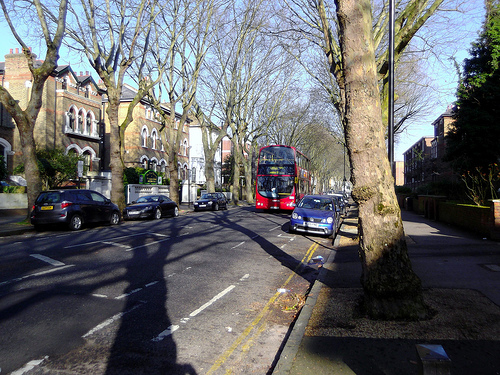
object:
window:
[63, 105, 78, 133]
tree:
[322, 0, 421, 315]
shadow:
[1, 204, 358, 374]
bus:
[253, 145, 314, 214]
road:
[0, 197, 495, 374]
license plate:
[40, 203, 57, 211]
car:
[291, 188, 344, 237]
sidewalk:
[269, 187, 498, 374]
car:
[26, 187, 125, 228]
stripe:
[54, 89, 101, 108]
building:
[0, 50, 190, 207]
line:
[147, 272, 250, 349]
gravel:
[300, 286, 499, 341]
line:
[208, 234, 324, 374]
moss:
[354, 178, 380, 204]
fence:
[130, 184, 177, 200]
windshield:
[256, 145, 295, 193]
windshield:
[299, 195, 344, 213]